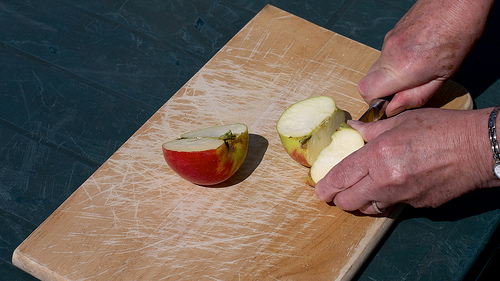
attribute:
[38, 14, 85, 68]
table — blue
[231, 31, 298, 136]
board — cutting, chopping, wooden, scratched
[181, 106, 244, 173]
apple — ripe, half, halved, cut, being, sliced, red, unpeeled, uneaten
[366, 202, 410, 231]
ring — wedding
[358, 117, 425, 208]
hand — holding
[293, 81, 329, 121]
surface — here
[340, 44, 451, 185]
hands — slicing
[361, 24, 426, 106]
person — cutting, slicing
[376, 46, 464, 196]
lady — wearing